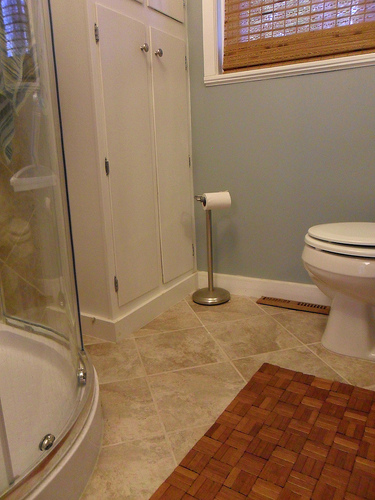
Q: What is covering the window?
A: A shade.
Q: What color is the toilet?
A: White.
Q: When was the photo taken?
A: Day time.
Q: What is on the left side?
A: Shower and cabinet.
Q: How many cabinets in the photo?
A: One.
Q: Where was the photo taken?
A: The bathroom.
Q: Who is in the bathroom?
A: Unoccupied.